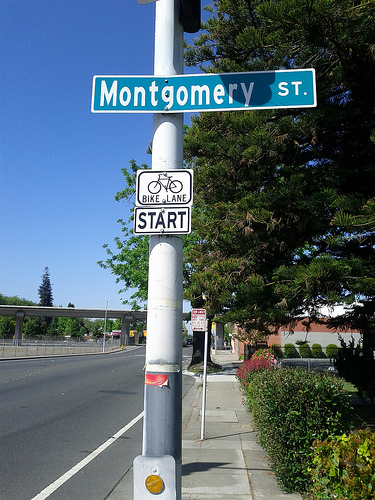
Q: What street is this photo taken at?
A: Montgomery St.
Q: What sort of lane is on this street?
A: Bike lane.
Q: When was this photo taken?
A: Daytime.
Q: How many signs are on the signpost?
A: Three.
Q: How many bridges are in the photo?
A: One.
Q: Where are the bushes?
A: Near the street.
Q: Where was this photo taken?
A: Near signs.